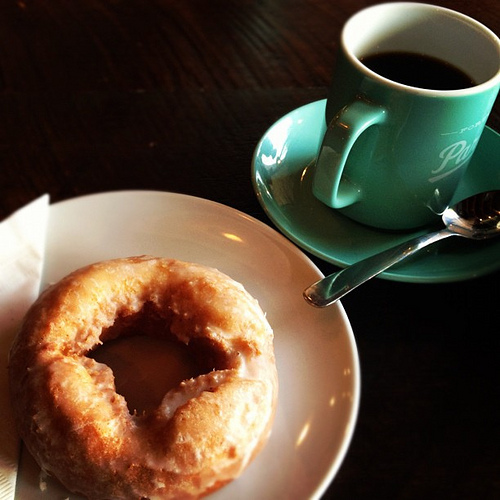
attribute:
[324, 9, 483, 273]
cup — green, coffe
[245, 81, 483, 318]
plate — green, small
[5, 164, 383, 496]
plate — white, round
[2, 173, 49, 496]
napkin — paper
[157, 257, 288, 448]
glaze — sweet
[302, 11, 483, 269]
cup — coffee, green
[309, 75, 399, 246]
handle — green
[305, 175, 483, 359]
spoon — silver metal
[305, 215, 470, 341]
handle — silver metal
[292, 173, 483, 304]
spoon — silver metal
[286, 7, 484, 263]
cup — coffee, green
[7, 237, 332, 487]
donut — brown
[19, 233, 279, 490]
donut — brown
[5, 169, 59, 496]
napkin — white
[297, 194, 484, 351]
spoon — silver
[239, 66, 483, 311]
plate — green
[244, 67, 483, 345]
plate — green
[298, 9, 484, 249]
cup — green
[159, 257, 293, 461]
glaze — sugar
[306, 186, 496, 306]
spoon — silver, tea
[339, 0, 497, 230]
mug — coffee, green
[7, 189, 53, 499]
napkin — white, paper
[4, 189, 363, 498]
plate — white, small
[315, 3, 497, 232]
mug — coffee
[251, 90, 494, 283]
saucer — matching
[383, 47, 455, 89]
coffee — black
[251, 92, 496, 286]
plate — green, small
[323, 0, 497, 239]
cup — green, coffee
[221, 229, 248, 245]
light — reflected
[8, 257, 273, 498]
donut — glazed 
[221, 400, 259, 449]
glaze — sugar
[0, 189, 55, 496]
napkin — white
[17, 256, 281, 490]
doughnut — brown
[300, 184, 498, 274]
spoon — silver 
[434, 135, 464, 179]
writing — white 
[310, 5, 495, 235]
coffee cup — green 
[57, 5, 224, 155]
table — brown , wooden 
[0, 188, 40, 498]
napkin — white , paper 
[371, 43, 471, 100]
coffee — black 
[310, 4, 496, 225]
cup — green 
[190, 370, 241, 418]
bubble — crispy , glazed 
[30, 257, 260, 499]
doughnut — brown 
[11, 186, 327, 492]
plate — shiny , reflective 